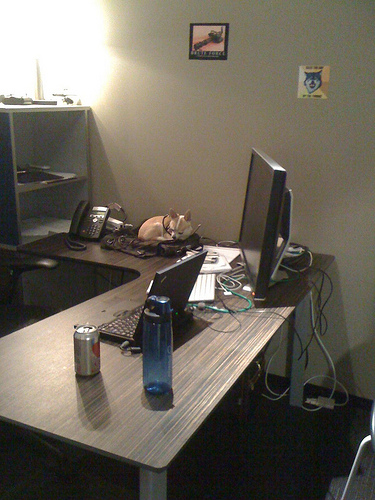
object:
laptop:
[98, 249, 208, 349]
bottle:
[142, 294, 171, 394]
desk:
[3, 251, 338, 471]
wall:
[0, 1, 372, 408]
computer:
[234, 148, 295, 303]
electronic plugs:
[305, 396, 336, 409]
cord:
[266, 236, 349, 412]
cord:
[216, 263, 252, 314]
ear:
[170, 207, 177, 218]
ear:
[184, 209, 191, 222]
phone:
[65, 201, 111, 251]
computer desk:
[0, 229, 335, 497]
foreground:
[0, 257, 333, 467]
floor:
[2, 368, 374, 498]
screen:
[241, 152, 270, 290]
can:
[73, 324, 100, 377]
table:
[0, 214, 329, 474]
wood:
[3, 218, 331, 469]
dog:
[138, 208, 193, 243]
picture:
[297, 66, 330, 99]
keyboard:
[188, 274, 215, 301]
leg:
[137, 467, 168, 498]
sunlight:
[3, 4, 103, 94]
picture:
[189, 23, 229, 60]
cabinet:
[1, 105, 91, 301]